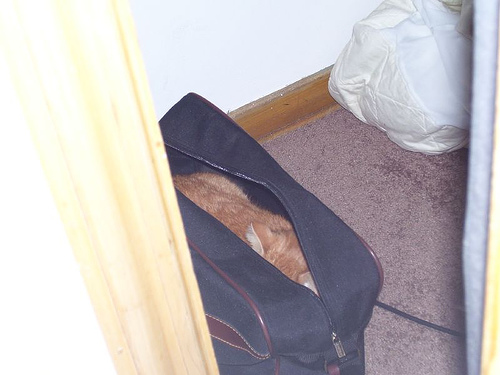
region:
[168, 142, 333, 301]
orange cat hiding in bag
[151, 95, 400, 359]
navy blue bag with burgundy stripe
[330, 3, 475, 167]
balled up white sheet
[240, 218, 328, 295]
ears of an orange cat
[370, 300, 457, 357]
black cord for an electronic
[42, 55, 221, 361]
light tan wooden door frame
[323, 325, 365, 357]
zipper handle on blue bag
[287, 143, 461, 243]
brown carpet on floor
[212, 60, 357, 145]
dark brown wall border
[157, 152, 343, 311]
orange cat asleep in bag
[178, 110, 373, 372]
this is a bag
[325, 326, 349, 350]
the zip is metallic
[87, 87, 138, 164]
the door is wooden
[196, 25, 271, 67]
this is the wall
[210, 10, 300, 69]
the wall is white in color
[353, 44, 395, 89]
this is a blanket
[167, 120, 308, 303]
orange cat in bag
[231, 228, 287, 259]
cat has orange ears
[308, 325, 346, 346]
bronze zipper on bag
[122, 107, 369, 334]
bag is dark blue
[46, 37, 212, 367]
wooden trim on door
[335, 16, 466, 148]
white bag behind blue bag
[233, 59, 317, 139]
brown wooden skirting board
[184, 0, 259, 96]
white wall behind bag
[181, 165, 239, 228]
cat has orange back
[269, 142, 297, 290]
Black bag on the ground with a cat.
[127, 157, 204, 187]
Black bag on the ground with a cat.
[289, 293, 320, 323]
Black bag on the ground with a cat.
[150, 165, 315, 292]
orange cat in bag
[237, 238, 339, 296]
cat has orange ears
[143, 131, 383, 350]
bag is blue and red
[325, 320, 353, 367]
zipper on outside of bag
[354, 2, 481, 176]
white blanket near wall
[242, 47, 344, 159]
brown skirting board on wall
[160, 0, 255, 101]
wall is white behind bag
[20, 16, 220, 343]
brown door frame near bag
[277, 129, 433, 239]
carpet is dark brown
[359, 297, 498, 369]
black cord near bag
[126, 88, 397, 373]
black bag with cat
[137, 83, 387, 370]
black bag with cat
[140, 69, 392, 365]
black bag with cat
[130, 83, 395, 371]
black bag with cat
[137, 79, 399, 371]
black bag with cat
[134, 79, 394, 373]
black bag with cat